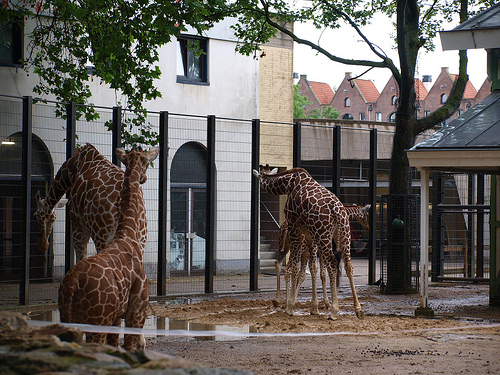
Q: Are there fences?
A: Yes, there is a fence.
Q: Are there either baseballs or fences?
A: Yes, there is a fence.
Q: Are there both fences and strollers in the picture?
A: No, there is a fence but no strollers.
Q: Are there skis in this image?
A: No, there are no skis.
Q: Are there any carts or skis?
A: No, there are no skis or carts.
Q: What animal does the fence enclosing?
A: The fence enclosing the giraffe.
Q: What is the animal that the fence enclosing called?
A: The animal is a giraffe.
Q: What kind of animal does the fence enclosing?
A: The fence enclosing the giraffe.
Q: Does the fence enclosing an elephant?
A: No, the fence enclosing a giraffe.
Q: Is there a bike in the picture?
A: No, there are no bikes.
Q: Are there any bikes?
A: No, there are no bikes.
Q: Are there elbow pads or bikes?
A: No, there are no bikes or elbow pads.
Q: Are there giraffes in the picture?
A: Yes, there is a giraffe.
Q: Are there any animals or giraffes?
A: Yes, there is a giraffe.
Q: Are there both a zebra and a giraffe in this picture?
A: No, there is a giraffe but no zebras.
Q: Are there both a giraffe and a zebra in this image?
A: No, there is a giraffe but no zebras.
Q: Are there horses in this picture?
A: No, there are no horses.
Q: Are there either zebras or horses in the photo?
A: No, there are no horses or zebras.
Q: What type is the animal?
A: The animal is a giraffe.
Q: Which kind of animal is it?
A: The animal is a giraffe.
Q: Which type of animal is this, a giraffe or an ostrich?
A: That is a giraffe.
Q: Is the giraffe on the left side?
A: Yes, the giraffe is on the left of the image.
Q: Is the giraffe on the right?
A: No, the giraffe is on the left of the image.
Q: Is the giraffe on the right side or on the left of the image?
A: The giraffe is on the left of the image.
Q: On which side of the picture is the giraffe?
A: The giraffe is on the left of the image.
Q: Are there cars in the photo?
A: No, there are no cars.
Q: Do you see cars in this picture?
A: No, there are no cars.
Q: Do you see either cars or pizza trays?
A: No, there are no cars or pizza trays.